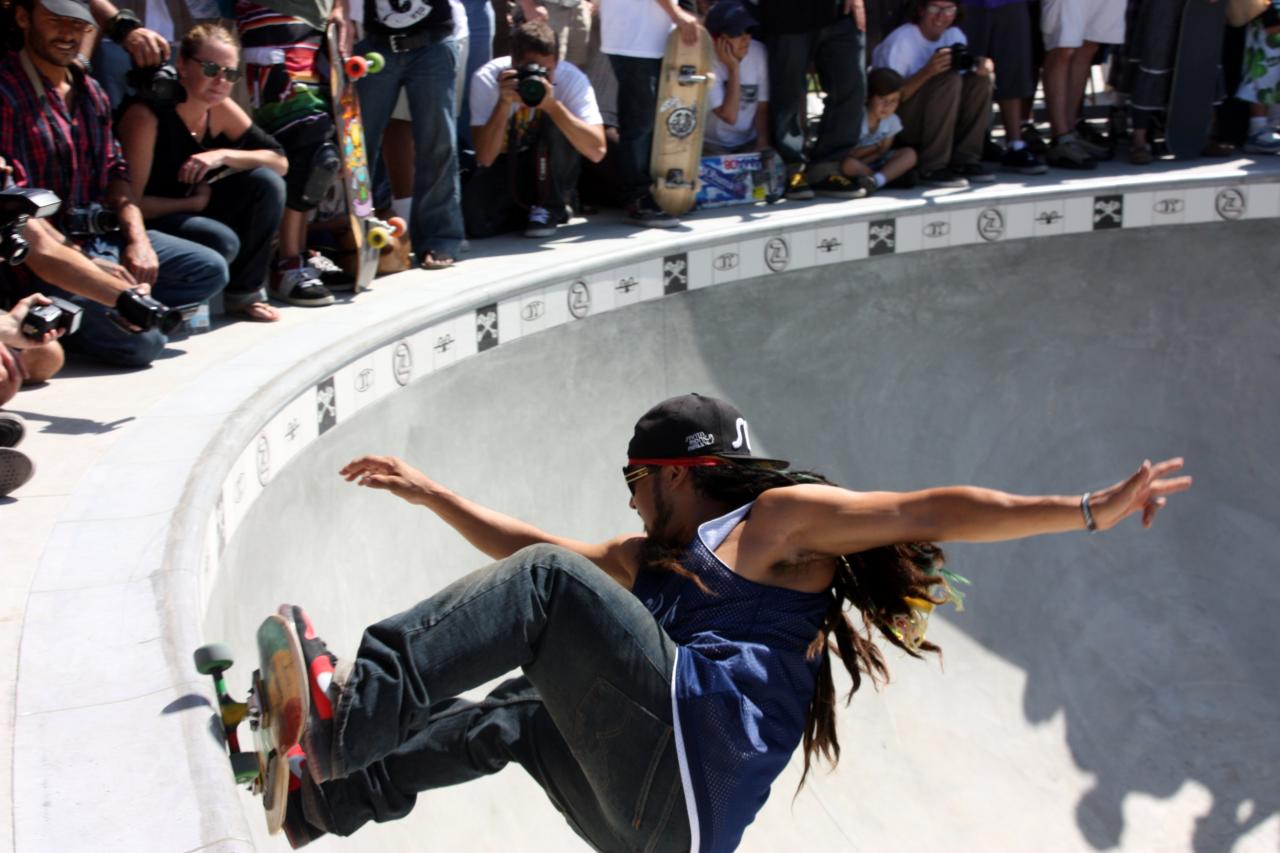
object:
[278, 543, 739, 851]
part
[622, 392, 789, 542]
part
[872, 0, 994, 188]
person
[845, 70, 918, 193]
person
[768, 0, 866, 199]
person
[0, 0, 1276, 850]
park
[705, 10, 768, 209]
person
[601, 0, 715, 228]
person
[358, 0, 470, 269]
person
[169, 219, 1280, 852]
ramp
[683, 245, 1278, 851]
shadow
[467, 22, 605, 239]
man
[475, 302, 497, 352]
photos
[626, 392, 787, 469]
cap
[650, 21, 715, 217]
wood skateboard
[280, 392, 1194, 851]
man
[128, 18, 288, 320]
woman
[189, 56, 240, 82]
black sunglasses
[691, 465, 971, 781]
hair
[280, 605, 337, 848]
shoes